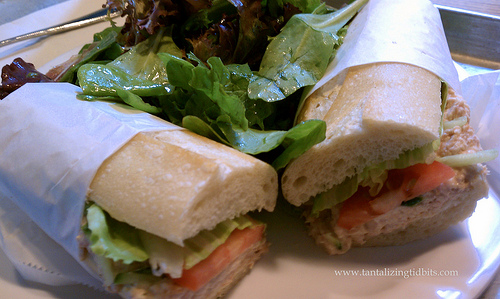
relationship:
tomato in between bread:
[205, 254, 226, 267] [304, 101, 403, 168]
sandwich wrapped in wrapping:
[292, 98, 444, 246] [0, 82, 190, 284]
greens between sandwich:
[157, 64, 233, 110] [292, 98, 444, 246]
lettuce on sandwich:
[88, 219, 125, 258] [292, 98, 444, 246]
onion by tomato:
[145, 246, 176, 275] [205, 254, 226, 267]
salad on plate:
[112, 4, 295, 120] [459, 271, 489, 290]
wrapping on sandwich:
[24, 110, 122, 166] [292, 98, 444, 246]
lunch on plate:
[100, 17, 383, 132] [459, 271, 489, 290]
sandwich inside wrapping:
[292, 98, 444, 246] [24, 110, 122, 166]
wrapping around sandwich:
[0, 82, 190, 284] [292, 98, 444, 246]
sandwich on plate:
[292, 98, 444, 246] [459, 271, 489, 290]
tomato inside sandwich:
[205, 254, 226, 267] [292, 98, 444, 246]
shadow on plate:
[277, 225, 306, 251] [459, 271, 489, 290]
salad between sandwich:
[112, 4, 295, 120] [292, 98, 444, 246]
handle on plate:
[65, 8, 112, 25] [459, 271, 489, 290]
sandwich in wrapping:
[292, 98, 444, 246] [0, 82, 190, 284]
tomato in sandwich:
[205, 254, 226, 267] [292, 98, 444, 246]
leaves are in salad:
[250, 0, 322, 85] [112, 4, 295, 120]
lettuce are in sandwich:
[88, 219, 125, 258] [292, 98, 444, 246]